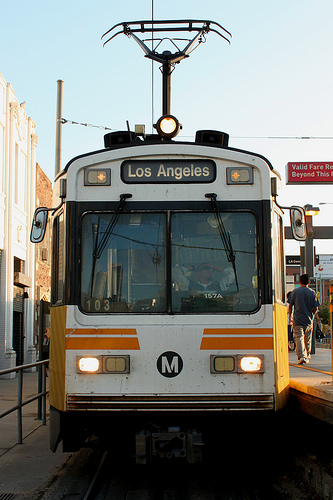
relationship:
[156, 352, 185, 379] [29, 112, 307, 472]
letter on train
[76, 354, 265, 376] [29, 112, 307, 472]
headlights on train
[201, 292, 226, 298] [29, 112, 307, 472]
number on train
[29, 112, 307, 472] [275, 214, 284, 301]
train has window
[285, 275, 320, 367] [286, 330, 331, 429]
man on sidewalk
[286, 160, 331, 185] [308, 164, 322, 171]
sign saying fare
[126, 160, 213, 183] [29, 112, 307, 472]
sign on train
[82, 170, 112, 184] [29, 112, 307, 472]
light on train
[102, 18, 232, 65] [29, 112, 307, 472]
conducts on train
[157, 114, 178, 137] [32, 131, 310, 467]
light on train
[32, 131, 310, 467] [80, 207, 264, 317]
train has window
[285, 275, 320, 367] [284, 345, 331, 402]
man on platform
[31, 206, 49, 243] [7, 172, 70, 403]
mirror on left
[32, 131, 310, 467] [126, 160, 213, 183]
train has sign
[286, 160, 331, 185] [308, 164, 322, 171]
sign has fare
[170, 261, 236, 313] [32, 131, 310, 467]
driver in train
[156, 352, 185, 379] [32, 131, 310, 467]
letter on train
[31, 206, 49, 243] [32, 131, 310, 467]
mirror on train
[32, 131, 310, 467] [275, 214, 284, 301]
train has window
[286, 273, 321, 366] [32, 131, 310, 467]
man near train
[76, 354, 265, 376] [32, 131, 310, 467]
headlights on train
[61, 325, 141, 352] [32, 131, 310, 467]
stripe on train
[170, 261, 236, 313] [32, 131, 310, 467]
driver on train